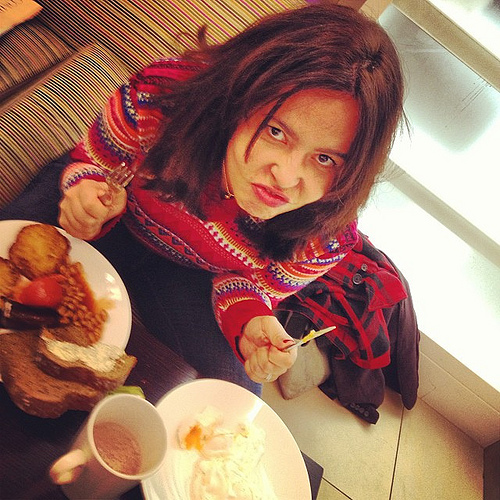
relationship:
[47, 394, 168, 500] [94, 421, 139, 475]
mug of cocoa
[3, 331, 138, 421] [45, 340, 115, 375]
toast with butter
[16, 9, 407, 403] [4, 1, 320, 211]
woman sitting on couch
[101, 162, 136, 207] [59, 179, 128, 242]
fork in hand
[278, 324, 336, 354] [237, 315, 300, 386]
knife in hand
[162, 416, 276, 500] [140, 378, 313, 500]
eggs on top of plate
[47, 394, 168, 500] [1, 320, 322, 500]
mug on top of table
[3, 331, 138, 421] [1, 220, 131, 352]
toast on top of plate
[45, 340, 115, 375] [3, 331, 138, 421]
butter on top of toast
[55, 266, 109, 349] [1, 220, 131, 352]
beans on top of plate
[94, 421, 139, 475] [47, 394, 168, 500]
cocoa in mug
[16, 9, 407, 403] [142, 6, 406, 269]
woman has hair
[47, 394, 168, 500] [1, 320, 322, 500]
mug on table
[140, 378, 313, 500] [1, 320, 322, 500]
plate on table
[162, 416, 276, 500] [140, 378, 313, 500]
eggs on plate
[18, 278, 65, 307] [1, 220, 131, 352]
tomato on plate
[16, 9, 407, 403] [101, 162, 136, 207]
woman holding fork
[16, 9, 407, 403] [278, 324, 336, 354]
woman holding knife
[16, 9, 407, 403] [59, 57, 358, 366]
woman has sweater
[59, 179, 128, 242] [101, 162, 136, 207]
hand clutching fork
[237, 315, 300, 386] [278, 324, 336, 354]
hand clutching knife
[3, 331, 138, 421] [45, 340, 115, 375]
toast has butter